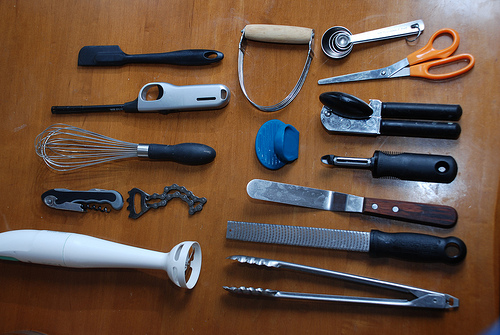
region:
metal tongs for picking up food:
[218, 253, 460, 313]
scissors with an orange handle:
[315, 28, 474, 85]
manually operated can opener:
[315, 91, 464, 142]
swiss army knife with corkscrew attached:
[37, 188, 121, 213]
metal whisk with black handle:
[32, 121, 221, 173]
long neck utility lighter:
[45, 80, 230, 116]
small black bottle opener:
[123, 183, 213, 218]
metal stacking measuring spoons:
[317, 18, 424, 60]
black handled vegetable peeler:
[317, 151, 462, 183]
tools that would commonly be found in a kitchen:
[5, 18, 473, 307]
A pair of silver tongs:
[217, 250, 471, 320]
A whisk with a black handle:
[28, 118, 226, 180]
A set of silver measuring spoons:
[315, 13, 430, 61]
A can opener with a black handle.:
[314, 88, 465, 145]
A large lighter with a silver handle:
[36, 78, 235, 122]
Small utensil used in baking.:
[245, 176, 471, 230]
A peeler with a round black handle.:
[316, 145, 468, 185]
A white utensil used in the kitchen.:
[1, 218, 207, 306]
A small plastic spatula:
[58, 30, 230, 80]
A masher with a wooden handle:
[226, 13, 319, 114]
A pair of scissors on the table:
[317, 26, 477, 85]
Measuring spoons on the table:
[318, 18, 426, 58]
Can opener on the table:
[318, 89, 463, 139]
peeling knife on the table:
[318, 149, 457, 182]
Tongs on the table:
[219, 253, 460, 310]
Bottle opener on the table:
[39, 186, 124, 213]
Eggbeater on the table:
[31, 121, 217, 172]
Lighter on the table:
[47, 81, 230, 115]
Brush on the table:
[76, 43, 224, 68]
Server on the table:
[243, 175, 459, 229]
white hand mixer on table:
[1, 223, 204, 293]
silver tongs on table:
[221, 250, 458, 315]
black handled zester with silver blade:
[223, 217, 471, 270]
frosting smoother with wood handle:
[244, 173, 461, 228]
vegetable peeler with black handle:
[315, 143, 459, 183]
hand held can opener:
[316, 88, 469, 141]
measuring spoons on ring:
[321, 20, 427, 59]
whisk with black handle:
[32, 119, 220, 176]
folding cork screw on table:
[38, 182, 125, 218]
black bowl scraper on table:
[73, 39, 226, 74]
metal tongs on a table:
[216, 249, 468, 330]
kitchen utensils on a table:
[16, 10, 469, 334]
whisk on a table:
[25, 115, 222, 183]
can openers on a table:
[40, 175, 215, 227]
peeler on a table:
[321, 142, 456, 192]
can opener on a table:
[307, 85, 472, 151]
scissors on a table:
[320, 33, 477, 92]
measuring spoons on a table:
[313, 9, 434, 66]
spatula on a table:
[68, 42, 231, 76]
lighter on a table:
[37, 75, 248, 119]